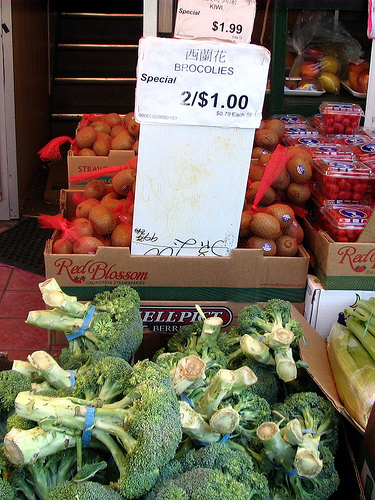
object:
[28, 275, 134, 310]
broccoli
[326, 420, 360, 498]
box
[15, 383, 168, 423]
broccoli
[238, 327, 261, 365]
broccoli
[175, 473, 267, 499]
broccoli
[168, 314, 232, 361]
broccoli